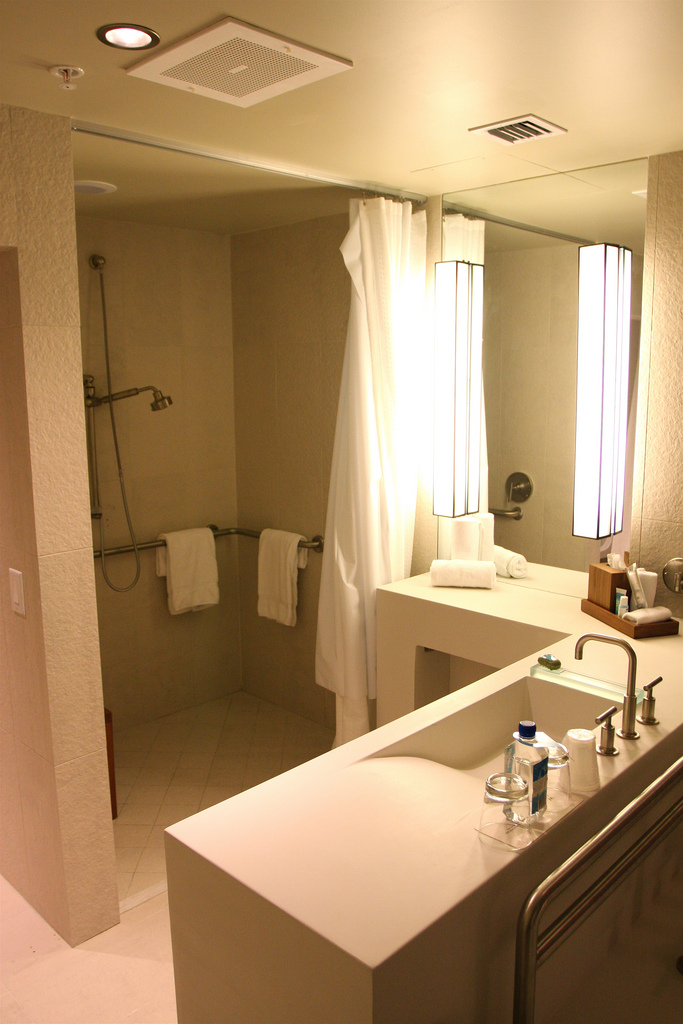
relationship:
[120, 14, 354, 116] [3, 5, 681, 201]
speaker in ceiling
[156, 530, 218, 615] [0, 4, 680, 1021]
towel hanging in bathroom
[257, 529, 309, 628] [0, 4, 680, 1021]
towel hanging in bathroom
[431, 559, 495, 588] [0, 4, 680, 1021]
towel hanging in bathroom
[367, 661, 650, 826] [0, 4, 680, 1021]
sink in bathroom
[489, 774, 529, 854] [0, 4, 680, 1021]
glass in bathroom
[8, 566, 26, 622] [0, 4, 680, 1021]
switch in bathroom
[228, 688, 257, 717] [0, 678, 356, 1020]
tile in floor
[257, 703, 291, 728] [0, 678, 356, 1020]
tile in floor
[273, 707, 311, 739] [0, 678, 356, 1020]
tile in floor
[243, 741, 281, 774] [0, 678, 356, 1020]
tile in floor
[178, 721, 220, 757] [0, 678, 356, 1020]
tile in floor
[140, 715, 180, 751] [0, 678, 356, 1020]
tile in floor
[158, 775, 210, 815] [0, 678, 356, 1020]
tile in floor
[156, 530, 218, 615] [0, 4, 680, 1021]
towel in bathroom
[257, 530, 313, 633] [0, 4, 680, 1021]
towel in bathroom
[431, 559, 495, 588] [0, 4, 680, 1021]
towel in bathroom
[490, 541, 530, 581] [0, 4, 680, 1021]
towel in bathroom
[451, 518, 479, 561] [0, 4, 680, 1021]
towel in bathroom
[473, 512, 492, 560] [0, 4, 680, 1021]
towel in bathroom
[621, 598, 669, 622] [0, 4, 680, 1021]
towel in bathroom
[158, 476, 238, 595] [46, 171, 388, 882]
towel hanging in shower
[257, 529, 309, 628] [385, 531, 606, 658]
towel on counter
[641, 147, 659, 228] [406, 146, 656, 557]
lights on mirror